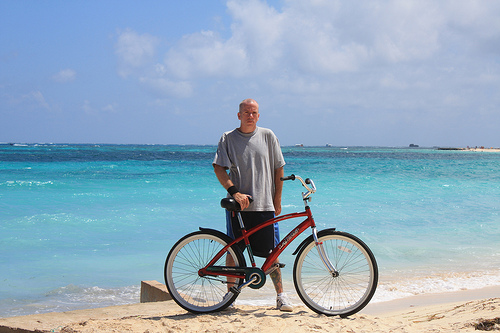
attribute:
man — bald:
[213, 96, 294, 314]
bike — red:
[164, 174, 379, 318]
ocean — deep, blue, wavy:
[1, 142, 497, 314]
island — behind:
[406, 143, 499, 154]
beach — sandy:
[0, 284, 497, 330]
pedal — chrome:
[228, 286, 241, 297]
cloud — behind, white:
[113, 2, 497, 105]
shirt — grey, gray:
[213, 127, 286, 214]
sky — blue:
[1, 1, 498, 149]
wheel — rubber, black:
[292, 230, 379, 319]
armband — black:
[227, 184, 241, 195]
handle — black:
[279, 173, 295, 181]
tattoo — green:
[267, 267, 281, 286]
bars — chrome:
[278, 174, 318, 197]